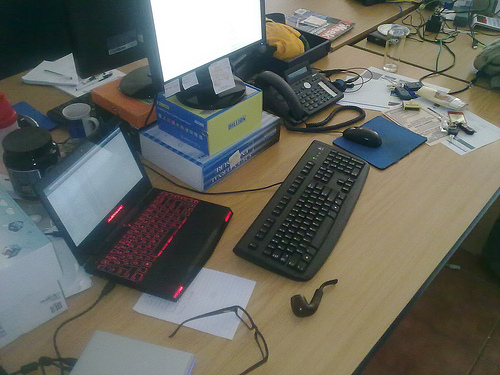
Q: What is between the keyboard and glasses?
A: Pipe.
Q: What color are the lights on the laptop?
A: Red.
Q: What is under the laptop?
A: Piece of paper.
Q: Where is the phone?
A: Desk.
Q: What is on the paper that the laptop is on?
A: Glasses.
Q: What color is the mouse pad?
A: Blue.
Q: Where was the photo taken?
A: In an office.